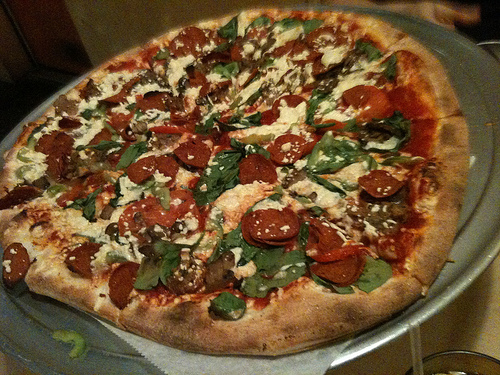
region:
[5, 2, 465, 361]
green basil on round pizza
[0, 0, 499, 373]
pizza sitting on white parchment paper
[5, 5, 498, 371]
round pizza on silver pan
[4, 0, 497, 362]
round pizza with pepperoni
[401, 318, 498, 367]
clear glass with plastic straw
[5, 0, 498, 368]
this is an indoor kitchen scene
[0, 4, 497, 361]
pizza with white cheese and golden brown crust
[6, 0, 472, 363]
basil pepperoni and mozzarella pizza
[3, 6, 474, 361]
traditional white pizza crust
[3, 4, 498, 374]
pizza is on a tray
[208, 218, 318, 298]
pizza has green leaves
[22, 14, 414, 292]
pizza has white cheese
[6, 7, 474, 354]
pizza is ready to eat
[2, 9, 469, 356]
pizza is round and ready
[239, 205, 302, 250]
pepperoni are on top of each other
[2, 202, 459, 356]
pizza crust is brown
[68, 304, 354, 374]
paper is under pizza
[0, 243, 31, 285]
pepperoni is falling off pizza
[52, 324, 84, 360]
green pepper is on the tray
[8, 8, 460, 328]
cooked pizza on a tray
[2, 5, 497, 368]
metal pan with pizza on it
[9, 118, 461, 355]
bottom half of pizza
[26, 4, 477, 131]
top half of pizza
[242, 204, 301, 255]
stacked pepperoni on a pizza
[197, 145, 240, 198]
green toppings in center of pizza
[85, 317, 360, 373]
white paper under pizza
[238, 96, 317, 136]
white cheese on pizza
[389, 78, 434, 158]
sauce on the pizza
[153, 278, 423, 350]
cooked pizza crust of the pizza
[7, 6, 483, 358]
pizza with toppings on silver tray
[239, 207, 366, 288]
pepperoni on cooked pizza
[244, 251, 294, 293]
pieces of spinach on pizza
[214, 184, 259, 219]
cheese on top of pizza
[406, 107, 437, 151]
tomato sauce on pizza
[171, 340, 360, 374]
white paper under pizza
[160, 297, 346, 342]
well done crust on pizza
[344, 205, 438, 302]
slice going through pizza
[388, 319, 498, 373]
glass with straw in it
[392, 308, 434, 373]
clear plastic straw in glass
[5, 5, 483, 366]
A pizza on a serving platter.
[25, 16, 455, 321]
Flecks of cheese are on the pizza.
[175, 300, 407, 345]
The crust is brown.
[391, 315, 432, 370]
A plastic straw.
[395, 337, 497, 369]
The rim of a glass.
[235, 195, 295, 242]
Pepperoni.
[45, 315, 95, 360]
A piece of green bell pepper.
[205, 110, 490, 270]
A slice has been cut.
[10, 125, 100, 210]
Pieces of green pepper on the pizza.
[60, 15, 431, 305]
The pizza has leaves of basil on it.